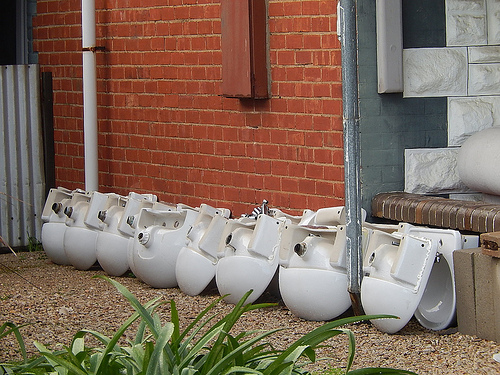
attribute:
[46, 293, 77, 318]
stone — small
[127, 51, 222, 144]
wall — bricks, red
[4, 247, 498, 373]
gravel — on ground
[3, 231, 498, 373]
ground — covered in gravel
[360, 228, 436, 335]
sink — whole lots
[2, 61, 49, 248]
fencing — small, grey, metal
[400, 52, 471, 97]
block — large, white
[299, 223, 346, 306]
sink — white, glass, leaning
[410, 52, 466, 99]
molds — ceramic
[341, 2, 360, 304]
pipe — metal, drain pipe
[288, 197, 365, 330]
washbasin — white, ceramic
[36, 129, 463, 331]
sink bowls — ceramic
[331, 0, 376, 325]
pipe — white color, plastic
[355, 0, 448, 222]
wall — grey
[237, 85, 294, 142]
wall — brick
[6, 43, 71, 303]
sheeting — corrugated metal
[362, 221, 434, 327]
sink — glass, white, leaning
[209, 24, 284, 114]
box — red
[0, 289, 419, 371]
grass — Small, patch, green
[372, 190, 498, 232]
porch — rusty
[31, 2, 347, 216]
brick wall — tall, on building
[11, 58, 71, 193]
fence — white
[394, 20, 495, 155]
tiles — white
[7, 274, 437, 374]
leaves — thin, green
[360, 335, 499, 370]
gravel — on ground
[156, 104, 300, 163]
bricks — red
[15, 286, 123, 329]
ground — covered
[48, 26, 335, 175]
building — brick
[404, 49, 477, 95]
brick — small